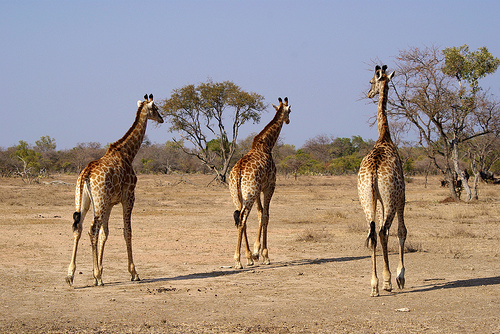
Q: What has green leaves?
A: A tree.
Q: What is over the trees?
A: Blue sky.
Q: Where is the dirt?
A: Under giraffes feet.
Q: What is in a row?
A: Three giraffes.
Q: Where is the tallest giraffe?
A: On the right.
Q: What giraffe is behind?
A: Giraffe on left side.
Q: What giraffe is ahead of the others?
A: Giraffe in middle of group.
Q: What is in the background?
A: Dead tree with little green.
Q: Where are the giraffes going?
A: Moving further away.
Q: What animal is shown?
A: Giraffe.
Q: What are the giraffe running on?
A: Dirt.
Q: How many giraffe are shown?
A: Three.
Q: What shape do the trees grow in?
A: Fan.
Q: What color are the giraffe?
A: Brown and white.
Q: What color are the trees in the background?
A: Green.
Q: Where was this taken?
A: Savannah.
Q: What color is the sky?
A: Blue.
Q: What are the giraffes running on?
A: Dirt.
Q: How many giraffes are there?
A: 3.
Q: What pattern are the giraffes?
A: Spots.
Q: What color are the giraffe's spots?
A: Brown.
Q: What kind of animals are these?
A: Giraffes.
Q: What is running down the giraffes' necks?
A: Manes.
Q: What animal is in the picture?
A: Giraffe.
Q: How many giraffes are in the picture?
A: Three.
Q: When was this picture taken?
A: During the day.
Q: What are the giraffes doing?
A: Walking.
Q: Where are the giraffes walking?
A: Toward the trees.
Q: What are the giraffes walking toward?
A: Trees.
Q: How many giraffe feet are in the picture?
A: Twelve.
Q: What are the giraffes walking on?
A: Dirt.